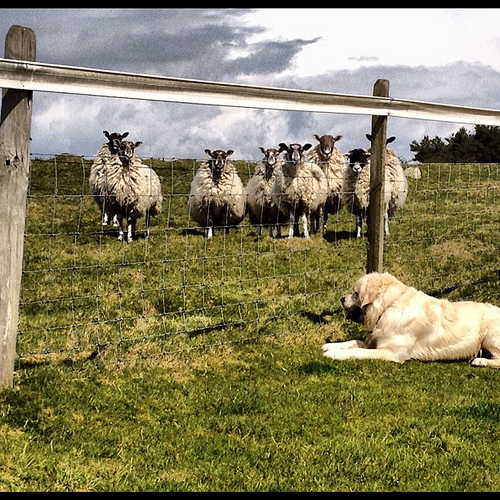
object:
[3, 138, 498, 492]
green pasture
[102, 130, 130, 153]
head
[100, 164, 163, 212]
body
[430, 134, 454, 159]
trees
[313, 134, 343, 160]
head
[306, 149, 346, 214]
sheep body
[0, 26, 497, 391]
railing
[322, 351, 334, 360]
paw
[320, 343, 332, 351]
paw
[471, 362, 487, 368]
paw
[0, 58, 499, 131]
rail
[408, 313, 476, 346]
cream colored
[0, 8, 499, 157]
cloudy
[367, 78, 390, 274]
post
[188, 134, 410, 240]
sheep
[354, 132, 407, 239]
white sheep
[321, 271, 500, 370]
dog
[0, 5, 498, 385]
fence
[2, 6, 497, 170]
sky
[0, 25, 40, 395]
pole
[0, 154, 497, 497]
grass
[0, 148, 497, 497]
field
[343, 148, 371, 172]
head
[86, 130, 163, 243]
sheep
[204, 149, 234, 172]
head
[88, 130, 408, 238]
flock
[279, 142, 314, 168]
head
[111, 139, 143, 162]
head